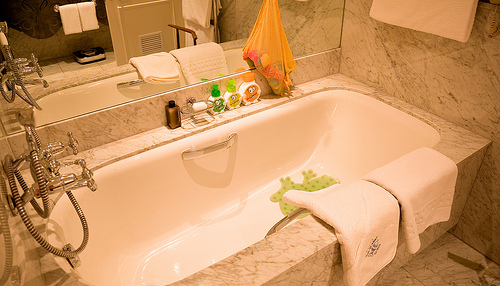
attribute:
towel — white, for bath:
[282, 177, 401, 285]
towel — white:
[363, 147, 460, 257]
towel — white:
[368, 0, 481, 44]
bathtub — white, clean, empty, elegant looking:
[0, 72, 492, 286]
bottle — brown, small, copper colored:
[165, 98, 182, 129]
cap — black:
[168, 99, 176, 108]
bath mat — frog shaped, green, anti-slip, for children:
[271, 170, 337, 216]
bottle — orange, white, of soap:
[241, 72, 262, 106]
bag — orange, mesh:
[240, 0, 297, 96]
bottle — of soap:
[224, 80, 242, 109]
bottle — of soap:
[208, 83, 226, 114]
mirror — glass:
[0, 0, 344, 139]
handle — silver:
[6, 160, 99, 221]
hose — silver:
[2, 134, 90, 262]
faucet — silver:
[0, 34, 100, 263]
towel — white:
[127, 48, 180, 85]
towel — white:
[170, 38, 229, 88]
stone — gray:
[0, 0, 500, 285]